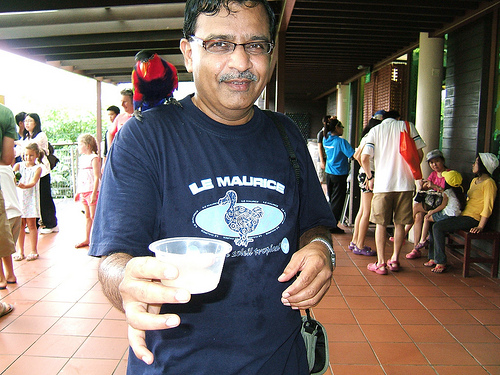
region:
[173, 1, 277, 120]
Man wearing clear spectacles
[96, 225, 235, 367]
Hand carrying a plastic container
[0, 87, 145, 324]
Group of people standing together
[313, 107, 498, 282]
Group of people either standing or sitting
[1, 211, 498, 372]
Smooth paved red pavement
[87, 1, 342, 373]
Man standing with a parrot on the shoulder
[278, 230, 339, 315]
Hand wearing a watch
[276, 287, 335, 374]
Small bag hanging on the side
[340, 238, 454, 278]
Sandles in the feet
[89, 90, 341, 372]
Blue shirt with branding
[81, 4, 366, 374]
man holding a cup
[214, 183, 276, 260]
duck image on man's shirt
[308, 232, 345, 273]
watch on man's wrist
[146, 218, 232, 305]
cup in man's hand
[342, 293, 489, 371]
brown tiled floor on ground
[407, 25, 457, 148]
column under a ceiling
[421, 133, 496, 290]
people sitting on a bench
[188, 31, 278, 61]
glasses on man's face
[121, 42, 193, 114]
bird on man's shoulder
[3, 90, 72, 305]
people standing on tile ground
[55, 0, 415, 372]
man holding clear cup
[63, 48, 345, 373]
man wearing blue graphic shirt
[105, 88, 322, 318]
white graphic on shirt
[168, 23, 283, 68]
man wearing pair of glasses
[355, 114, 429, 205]
person wearing white shirt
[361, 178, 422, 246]
person wearing brown shorts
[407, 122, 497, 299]
person sitting in chair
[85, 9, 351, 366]
person has bird on shoulder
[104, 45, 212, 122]
bird is red on black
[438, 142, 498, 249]
person wearing yellow shirt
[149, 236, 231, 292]
clear plastic cup in hand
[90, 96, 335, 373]
blue cotton tee shirt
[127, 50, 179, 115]
red and black bird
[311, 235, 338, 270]
metal watch on wrist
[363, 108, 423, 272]
man holding orange bag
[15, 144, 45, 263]
girl wearing white dress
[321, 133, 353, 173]
blue hooded sweat shirt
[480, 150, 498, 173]
white knit winter hat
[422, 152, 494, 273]
woman sitting on chair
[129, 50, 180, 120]
bird on mans shoulder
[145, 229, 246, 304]
plastic container in a man's hand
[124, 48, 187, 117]
red and black colored bird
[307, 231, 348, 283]
watch on the wrist of the man posing for the camera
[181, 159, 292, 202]
words "le maurice" on a man's blue shirt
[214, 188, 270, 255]
bird on a man's shirt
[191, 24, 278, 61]
glasses on a man's face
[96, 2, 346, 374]
man with a bird on his shoulder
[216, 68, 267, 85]
grey moustache on a man's face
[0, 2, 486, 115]
beams of the ceiling of the covered area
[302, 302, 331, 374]
man's black and grey colored bag